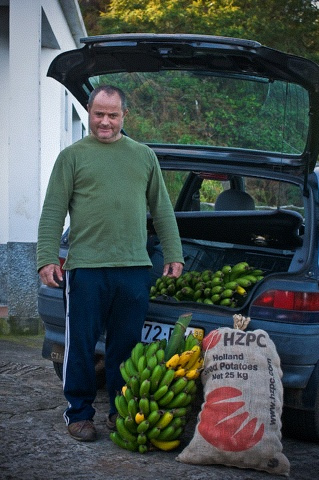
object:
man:
[36, 84, 186, 442]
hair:
[87, 85, 127, 116]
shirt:
[36, 132, 186, 273]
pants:
[62, 265, 153, 427]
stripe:
[62, 270, 73, 427]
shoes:
[66, 414, 119, 442]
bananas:
[109, 312, 205, 455]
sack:
[175, 314, 291, 478]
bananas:
[149, 261, 265, 309]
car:
[37, 29, 319, 442]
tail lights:
[249, 288, 319, 324]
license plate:
[141, 320, 205, 350]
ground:
[0, 335, 317, 480]